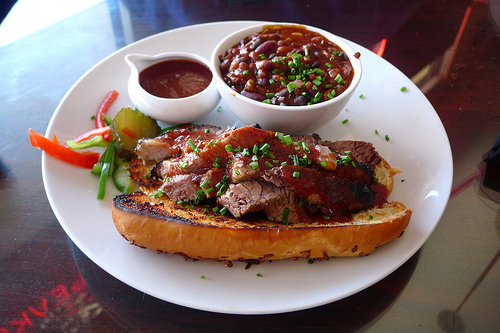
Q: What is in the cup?
A: Sauce.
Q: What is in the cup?
A: Sauce.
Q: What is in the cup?
A: Food.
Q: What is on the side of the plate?
A: Vegetables.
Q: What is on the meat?
A: Chives.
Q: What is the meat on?
A: Bread.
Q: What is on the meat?
A: Sauce.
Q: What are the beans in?
A: Bowl.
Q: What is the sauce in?
A: Cup.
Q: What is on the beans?
A: Chives.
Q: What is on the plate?
A: Food.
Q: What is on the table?
A: Plate.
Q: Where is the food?
A: On the plate.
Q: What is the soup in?
A: A white bowl.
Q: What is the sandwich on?
A: A white plate.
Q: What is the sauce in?
A: A white sauce cup.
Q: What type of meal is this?
A: Lunch.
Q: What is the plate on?
A: A black reflective table.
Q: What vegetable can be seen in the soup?
A: Beans.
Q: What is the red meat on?
A: A bread bun.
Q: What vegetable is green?
A: Green beans.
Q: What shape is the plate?
A: A circle.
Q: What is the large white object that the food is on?
A: Plate.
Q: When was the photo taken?
A: At lunch.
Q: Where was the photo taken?
A: At a restaurant.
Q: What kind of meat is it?
A: Beef.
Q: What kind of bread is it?
A: French bread.